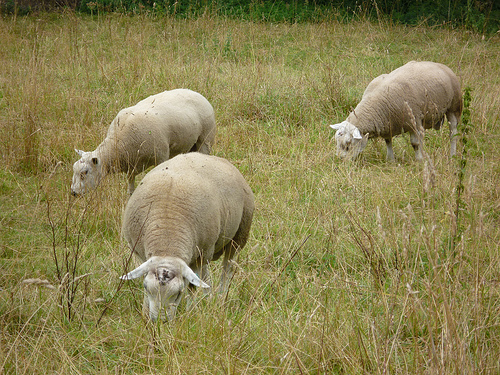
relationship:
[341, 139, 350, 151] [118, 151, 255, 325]
eye on sheep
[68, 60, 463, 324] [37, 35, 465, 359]
sheep in field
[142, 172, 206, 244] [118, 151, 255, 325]
fleece on sheep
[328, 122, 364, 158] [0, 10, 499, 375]
head to ground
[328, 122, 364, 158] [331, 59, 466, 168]
head on sheep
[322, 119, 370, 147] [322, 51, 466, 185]
ears on sheep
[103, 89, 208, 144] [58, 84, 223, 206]
body on sheep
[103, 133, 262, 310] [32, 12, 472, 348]
sheep in pasture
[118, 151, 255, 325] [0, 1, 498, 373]
sheep eating grass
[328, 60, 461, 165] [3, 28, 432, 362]
sheep eating grass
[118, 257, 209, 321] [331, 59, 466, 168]
head of sheep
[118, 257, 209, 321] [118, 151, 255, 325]
head of sheep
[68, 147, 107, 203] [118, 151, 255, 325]
head of sheep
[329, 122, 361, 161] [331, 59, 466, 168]
head of sheep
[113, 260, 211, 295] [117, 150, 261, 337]
ears of sheep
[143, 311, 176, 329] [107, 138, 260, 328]
nose of sheep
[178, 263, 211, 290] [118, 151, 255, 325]
ear of sheep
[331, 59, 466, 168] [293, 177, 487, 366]
sheep in grass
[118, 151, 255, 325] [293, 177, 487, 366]
sheep in grass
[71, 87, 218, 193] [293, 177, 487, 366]
sheep in grass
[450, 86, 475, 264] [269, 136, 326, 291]
plant growing in grass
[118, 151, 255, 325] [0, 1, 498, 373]
sheep eat grass